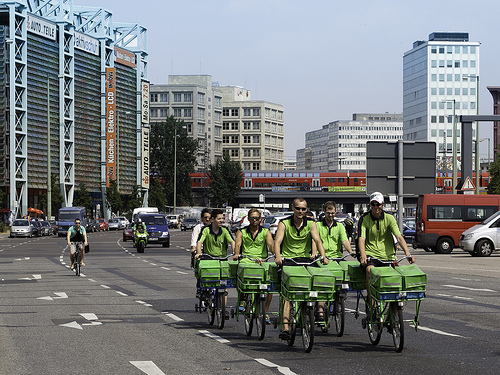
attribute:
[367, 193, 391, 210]
cap — white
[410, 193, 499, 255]
van — red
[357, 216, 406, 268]
shirt — black, green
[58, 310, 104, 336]
arrow — white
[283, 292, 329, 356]
bike — green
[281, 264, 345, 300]
basket — green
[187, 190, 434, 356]
men — biking, grouped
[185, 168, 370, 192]
train — red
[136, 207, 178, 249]
car — moving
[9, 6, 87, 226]
building — blue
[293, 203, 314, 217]
sunglasses — black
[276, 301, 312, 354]
bicycle — green